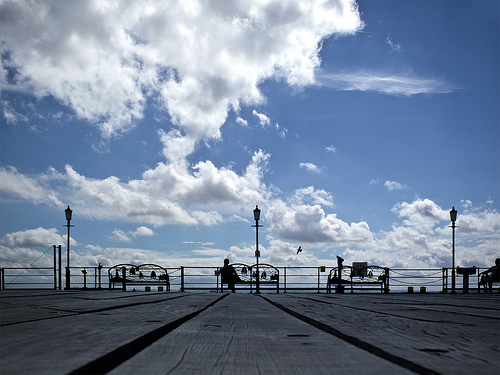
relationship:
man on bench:
[225, 254, 245, 274] [204, 251, 287, 293]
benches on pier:
[104, 260, 392, 290] [0, 291, 499, 374]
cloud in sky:
[0, 0, 363, 133] [8, 1, 496, 290]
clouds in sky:
[284, 191, 439, 256] [8, 1, 496, 290]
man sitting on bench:
[213, 259, 242, 292] [215, 262, 281, 294]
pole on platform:
[444, 204, 456, 294] [0, 284, 494, 371]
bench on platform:
[118, 265, 180, 301] [115, 278, 207, 329]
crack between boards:
[154, 319, 180, 340] [99, 294, 218, 373]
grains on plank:
[148, 339, 243, 366] [105, 292, 416, 374]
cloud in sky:
[0, 0, 363, 133] [229, 58, 359, 158]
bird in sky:
[287, 231, 310, 260] [306, 104, 396, 209]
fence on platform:
[0, 265, 500, 293] [39, 289, 101, 335]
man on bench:
[213, 259, 242, 292] [228, 258, 308, 305]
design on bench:
[96, 258, 164, 290] [99, 253, 192, 307]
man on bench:
[213, 259, 242, 292] [225, 261, 287, 291]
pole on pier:
[235, 201, 276, 302] [145, 289, 272, 372]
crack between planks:
[64, 291, 233, 374] [124, 317, 270, 371]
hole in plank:
[286, 323, 326, 346] [205, 291, 335, 348]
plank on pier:
[158, 317, 281, 351] [104, 311, 302, 353]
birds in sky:
[287, 239, 324, 260] [306, 110, 401, 190]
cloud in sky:
[110, 44, 255, 116] [303, 114, 404, 182]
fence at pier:
[17, 262, 87, 290] [58, 290, 178, 336]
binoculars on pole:
[318, 245, 358, 273] [321, 196, 390, 346]